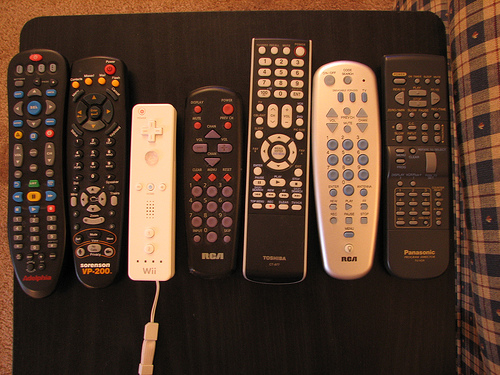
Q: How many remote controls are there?
A: Seven.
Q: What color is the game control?
A: White.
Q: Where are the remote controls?
A: Table.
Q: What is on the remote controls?
A: Buttons.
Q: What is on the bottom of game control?
A: Wire.